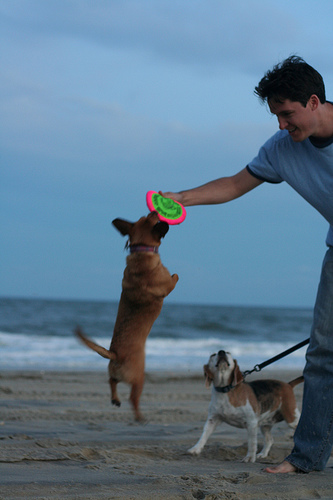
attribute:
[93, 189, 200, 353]
dog — small, brown, leash, jumping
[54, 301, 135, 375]
tail — small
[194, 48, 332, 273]
guy — mid-thirties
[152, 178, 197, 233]
frisbee — small, green, playing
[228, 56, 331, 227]
man — holding, barefoot, head, standing, bare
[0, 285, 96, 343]
water — coming, white, large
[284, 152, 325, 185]
shirt — blue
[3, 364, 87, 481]
beach — wet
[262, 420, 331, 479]
foot — bare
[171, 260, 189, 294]
paw — white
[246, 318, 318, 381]
leash — black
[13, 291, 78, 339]
ocean — blue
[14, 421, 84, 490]
tire — print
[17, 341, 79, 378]
wave — white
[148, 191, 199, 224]
saucer — green